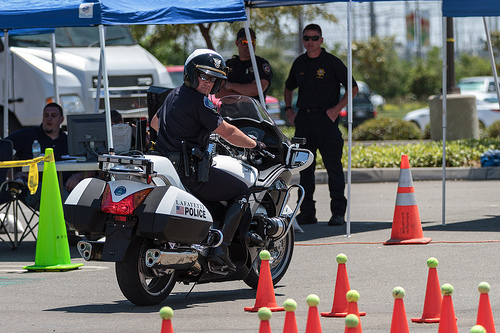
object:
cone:
[242, 258, 282, 311]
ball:
[158, 306, 175, 320]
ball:
[258, 247, 270, 261]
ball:
[256, 305, 273, 320]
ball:
[282, 297, 297, 312]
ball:
[306, 292, 320, 306]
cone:
[322, 264, 364, 316]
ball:
[335, 252, 347, 263]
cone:
[381, 151, 431, 244]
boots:
[209, 197, 251, 265]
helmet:
[182, 43, 233, 92]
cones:
[383, 297, 410, 332]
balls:
[306, 292, 321, 304]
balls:
[475, 279, 490, 294]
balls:
[156, 303, 177, 320]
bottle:
[27, 137, 42, 159]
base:
[429, 94, 474, 141]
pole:
[444, 9, 456, 89]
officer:
[284, 18, 355, 233]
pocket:
[323, 110, 339, 132]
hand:
[327, 109, 336, 124]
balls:
[461, 323, 497, 332]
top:
[426, 267, 439, 285]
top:
[480, 293, 489, 305]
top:
[395, 297, 403, 307]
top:
[344, 302, 359, 310]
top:
[256, 322, 271, 329]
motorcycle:
[101, 91, 317, 308]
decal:
[171, 199, 215, 220]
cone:
[432, 291, 457, 331]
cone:
[387, 297, 412, 332]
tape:
[392, 167, 417, 187]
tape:
[392, 190, 422, 208]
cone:
[318, 251, 368, 315]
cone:
[23, 146, 83, 273]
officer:
[137, 48, 275, 278]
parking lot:
[4, 147, 497, 330]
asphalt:
[332, 235, 438, 271]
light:
[97, 182, 161, 217]